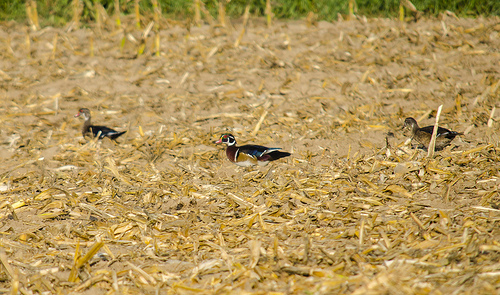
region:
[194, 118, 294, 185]
small duck in center of photo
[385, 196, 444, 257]
light brown mulch on right of photo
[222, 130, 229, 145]
red eye on ducks face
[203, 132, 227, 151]
orange beaks on front of duck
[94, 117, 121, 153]
dark feathers on back of duck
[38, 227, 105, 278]
light brown mulch on front right of photo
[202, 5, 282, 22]
green grass in back of photo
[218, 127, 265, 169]
stripes on back of ducks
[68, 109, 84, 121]
orange beak on duck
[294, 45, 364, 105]
brown mulch in the center of photo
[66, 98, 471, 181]
three ducks walking on yellow straw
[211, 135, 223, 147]
orange beak of duck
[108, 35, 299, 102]
patch of yellow straw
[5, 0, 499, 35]
green grass in front of yellow straw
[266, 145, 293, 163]
dark brown tail of duck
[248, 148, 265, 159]
green section of duck wing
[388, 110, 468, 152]
brown tan and white duck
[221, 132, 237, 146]
white stripes on duck's head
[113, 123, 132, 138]
black upturned tail of duck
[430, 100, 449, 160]
blade of tan upright straw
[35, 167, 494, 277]
the ground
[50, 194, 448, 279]
wood chips on the ground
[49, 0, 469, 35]
tall grass in the distance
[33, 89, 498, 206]
three birds in the field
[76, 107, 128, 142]
a bird with a white face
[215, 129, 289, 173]
a bird walking in the wood chips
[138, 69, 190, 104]
dirt on the ground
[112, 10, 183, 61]
weeds in the dirt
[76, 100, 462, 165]
birds all walking the same direction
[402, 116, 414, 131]
the face of the bird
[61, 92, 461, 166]
three birds on the ground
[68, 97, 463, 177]
group of three birds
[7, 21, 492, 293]
brown dirt on the ground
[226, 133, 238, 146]
skinny white stripes on the face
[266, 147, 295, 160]
long, dark feathers on the tail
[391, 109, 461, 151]
side profile of a bird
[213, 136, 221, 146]
small orange beak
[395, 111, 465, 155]
black and brown bird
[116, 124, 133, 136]
tail of the bird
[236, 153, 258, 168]
belly is light brown and white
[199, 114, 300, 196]
this is a bird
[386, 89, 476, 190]
this is a bird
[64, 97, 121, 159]
this is a bird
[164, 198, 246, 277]
these are dried leaves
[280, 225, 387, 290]
these are dried leaves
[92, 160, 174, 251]
these are dried leaves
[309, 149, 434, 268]
these are dried leaves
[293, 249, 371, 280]
these are dried leaves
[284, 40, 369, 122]
these are dried leaves